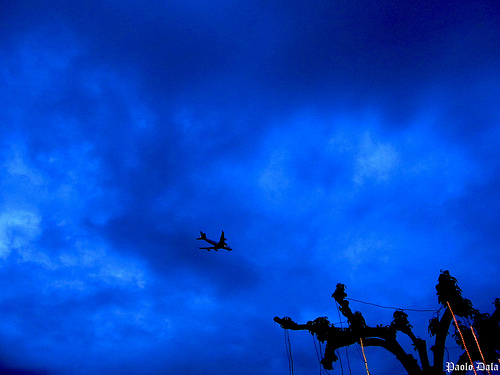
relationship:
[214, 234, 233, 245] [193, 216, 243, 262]
wing of plane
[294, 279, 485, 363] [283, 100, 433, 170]
tree underneath a dark cloudy sky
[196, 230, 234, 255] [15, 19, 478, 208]
plane in air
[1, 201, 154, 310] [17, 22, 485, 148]
clouds in sky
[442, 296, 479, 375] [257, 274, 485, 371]
lights hanging on tree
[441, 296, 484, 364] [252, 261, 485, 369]
lights hanging from tree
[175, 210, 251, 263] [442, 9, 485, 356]
plane flying towards right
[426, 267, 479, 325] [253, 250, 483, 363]
leaves on tree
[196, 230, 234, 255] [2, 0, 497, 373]
plane in sky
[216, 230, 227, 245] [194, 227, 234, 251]
wing on plane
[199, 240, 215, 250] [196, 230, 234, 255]
wing on plane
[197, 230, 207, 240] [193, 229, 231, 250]
tail on plane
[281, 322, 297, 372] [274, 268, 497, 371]
string on tree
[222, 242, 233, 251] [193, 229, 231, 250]
nose on plane